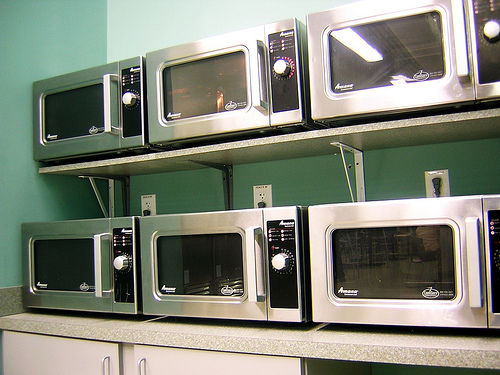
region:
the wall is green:
[1, 2, 497, 284]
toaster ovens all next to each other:
[8, 14, 497, 352]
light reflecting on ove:
[328, 25, 385, 70]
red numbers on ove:
[268, 54, 299, 81]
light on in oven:
[163, 51, 256, 123]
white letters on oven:
[163, 109, 186, 125]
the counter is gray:
[3, 282, 498, 367]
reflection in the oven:
[328, 229, 452, 279]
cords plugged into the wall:
[123, 164, 463, 219]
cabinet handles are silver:
[91, 345, 153, 373]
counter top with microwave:
[18, 310, 224, 346]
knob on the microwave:
[265, 247, 300, 279]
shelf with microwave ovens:
[45, 97, 382, 166]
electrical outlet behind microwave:
[248, 177, 275, 205]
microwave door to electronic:
[131, 215, 263, 316]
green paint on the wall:
[2, 165, 60, 208]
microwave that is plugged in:
[138, 215, 309, 322]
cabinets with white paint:
[6, 335, 110, 374]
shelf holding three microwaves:
[258, 117, 423, 148]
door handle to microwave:
[238, 229, 270, 299]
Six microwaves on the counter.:
[23, 47, 495, 335]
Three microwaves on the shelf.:
[9, 2, 484, 138]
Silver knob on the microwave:
[261, 251, 304, 276]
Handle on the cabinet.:
[96, 346, 116, 374]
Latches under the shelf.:
[332, 136, 372, 198]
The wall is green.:
[13, 0, 172, 66]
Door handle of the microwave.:
[236, 35, 273, 107]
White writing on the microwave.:
[336, 272, 364, 302]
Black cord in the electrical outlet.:
[426, 167, 448, 194]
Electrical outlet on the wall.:
[248, 176, 283, 208]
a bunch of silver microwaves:
[14, 49, 446, 340]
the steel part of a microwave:
[134, 212, 289, 236]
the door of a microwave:
[140, 211, 275, 326]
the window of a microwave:
[157, 231, 247, 301]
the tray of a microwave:
[194, 285, 235, 302]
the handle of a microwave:
[240, 219, 260, 309]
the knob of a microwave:
[260, 246, 298, 280]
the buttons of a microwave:
[261, 218, 303, 249]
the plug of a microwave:
[240, 198, 275, 213]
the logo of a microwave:
[147, 285, 187, 300]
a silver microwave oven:
[21, 214, 146, 318]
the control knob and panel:
[265, 218, 304, 327]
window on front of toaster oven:
[148, 224, 249, 307]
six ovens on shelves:
[2, 2, 499, 331]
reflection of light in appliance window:
[314, 19, 452, 85]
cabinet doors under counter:
[0, 341, 307, 373]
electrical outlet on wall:
[248, 183, 279, 207]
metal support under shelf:
[329, 138, 376, 202]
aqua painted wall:
[11, 12, 93, 57]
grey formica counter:
[305, 336, 491, 367]